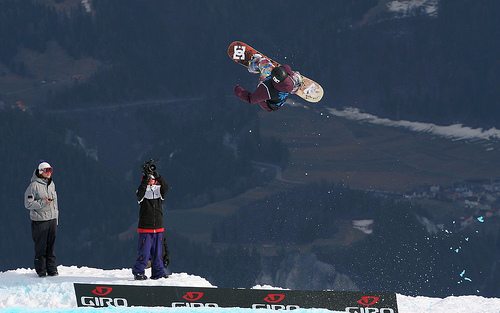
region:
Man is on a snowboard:
[208, 30, 331, 128]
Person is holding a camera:
[131, 150, 177, 277]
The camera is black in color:
[133, 152, 164, 183]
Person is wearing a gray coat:
[20, 160, 67, 225]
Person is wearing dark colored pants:
[25, 212, 65, 277]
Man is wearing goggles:
[35, 157, 56, 173]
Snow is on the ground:
[2, 262, 497, 310]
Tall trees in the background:
[0, 0, 497, 246]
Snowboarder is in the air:
[213, 30, 331, 136]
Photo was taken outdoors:
[4, 2, 493, 307]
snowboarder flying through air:
[225, 38, 323, 110]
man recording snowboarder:
[132, 155, 168, 276]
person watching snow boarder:
[23, 160, 60, 276]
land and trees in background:
[0, 0, 499, 296]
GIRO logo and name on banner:
[77, 283, 126, 307]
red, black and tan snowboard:
[226, 41, 323, 101]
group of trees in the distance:
[210, 178, 369, 238]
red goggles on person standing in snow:
[43, 168, 53, 174]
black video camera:
[141, 157, 159, 174]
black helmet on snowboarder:
[271, 66, 289, 81]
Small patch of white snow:
[36, 293, 51, 302]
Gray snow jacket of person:
[33, 184, 46, 196]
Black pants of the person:
[35, 230, 55, 250]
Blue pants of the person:
[143, 244, 162, 266]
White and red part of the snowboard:
[231, 40, 248, 63]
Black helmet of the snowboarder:
[273, 67, 287, 79]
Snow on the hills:
[456, 125, 481, 138]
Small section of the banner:
[81, 284, 133, 306]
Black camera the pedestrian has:
[145, 158, 160, 175]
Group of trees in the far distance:
[186, 153, 220, 183]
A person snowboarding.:
[221, 41, 325, 111]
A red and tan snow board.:
[223, 39, 323, 101]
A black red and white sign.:
[71, 282, 397, 312]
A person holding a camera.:
[132, 154, 172, 279]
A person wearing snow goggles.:
[23, 160, 61, 278]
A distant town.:
[399, 175, 499, 236]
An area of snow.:
[0, 264, 499, 311]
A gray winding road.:
[238, 157, 317, 188]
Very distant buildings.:
[7, 98, 33, 115]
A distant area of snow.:
[280, 95, 499, 148]